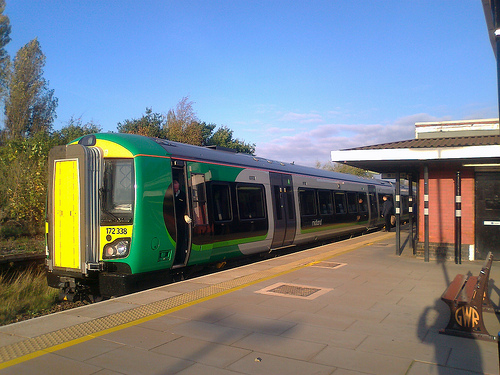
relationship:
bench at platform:
[409, 246, 498, 342] [396, 215, 477, 342]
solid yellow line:
[167, 291, 222, 314] [153, 302, 202, 327]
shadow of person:
[417, 229, 475, 374] [409, 246, 498, 342]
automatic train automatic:
[257, 141, 317, 264] [268, 171, 298, 249]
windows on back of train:
[204, 169, 275, 224] [45, 128, 417, 301]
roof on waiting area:
[313, 83, 499, 173] [365, 155, 481, 358]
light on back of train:
[103, 224, 131, 262] [101, 228, 137, 271]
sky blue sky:
[0, 0, 500, 150] [223, 18, 362, 94]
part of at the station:
[41, 134, 189, 300] [0, 117, 499, 373]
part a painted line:
[41, 134, 189, 300] [217, 275, 310, 299]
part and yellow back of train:
[41, 134, 189, 300] [45, 128, 417, 301]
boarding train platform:
[146, 204, 390, 311] [396, 215, 477, 342]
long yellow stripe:
[143, 275, 288, 298] [132, 295, 250, 320]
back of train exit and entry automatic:
[45, 128, 417, 301] [268, 171, 298, 249]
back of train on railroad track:
[45, 128, 417, 301] [81, 138, 406, 271]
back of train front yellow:
[45, 128, 417, 301] [58, 166, 80, 229]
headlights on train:
[101, 228, 137, 271] [103, 224, 131, 262]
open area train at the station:
[327, 261, 419, 285] [0, 117, 499, 373]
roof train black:
[330, 116, 500, 173] [169, 143, 266, 162]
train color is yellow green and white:
[72, 148, 354, 244] [81, 138, 406, 271]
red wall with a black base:
[406, 227, 475, 273] [421, 210, 460, 289]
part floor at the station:
[41, 134, 189, 300] [352, 247, 389, 292]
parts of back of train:
[72, 148, 354, 244] [45, 128, 417, 301]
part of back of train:
[163, 134, 344, 230] [45, 128, 417, 301]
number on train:
[101, 221, 140, 243] [37, 120, 415, 300]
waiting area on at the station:
[365, 155, 481, 358] [0, 117, 499, 373]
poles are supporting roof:
[411, 165, 480, 270] [334, 118, 498, 199]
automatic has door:
[268, 171, 298, 249] [265, 166, 301, 245]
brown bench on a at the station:
[458, 269, 489, 294] [0, 117, 499, 373]